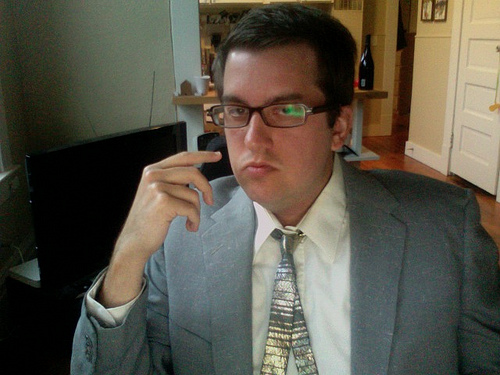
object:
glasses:
[208, 100, 353, 129]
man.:
[68, 4, 499, 374]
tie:
[260, 228, 319, 374]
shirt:
[252, 151, 352, 374]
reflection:
[283, 104, 304, 117]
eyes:
[276, 107, 296, 115]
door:
[448, 0, 499, 198]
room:
[0, 2, 499, 286]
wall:
[0, 1, 174, 278]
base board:
[404, 109, 450, 177]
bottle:
[358, 33, 374, 92]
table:
[173, 87, 388, 168]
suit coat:
[71, 156, 500, 374]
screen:
[45, 130, 182, 266]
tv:
[21, 118, 189, 303]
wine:
[359, 47, 374, 89]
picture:
[432, 0, 449, 23]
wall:
[406, 1, 453, 157]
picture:
[419, 0, 433, 23]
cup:
[194, 74, 211, 97]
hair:
[212, 3, 355, 130]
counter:
[170, 80, 390, 105]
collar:
[252, 155, 344, 268]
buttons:
[295, 260, 307, 271]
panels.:
[463, 38, 500, 69]